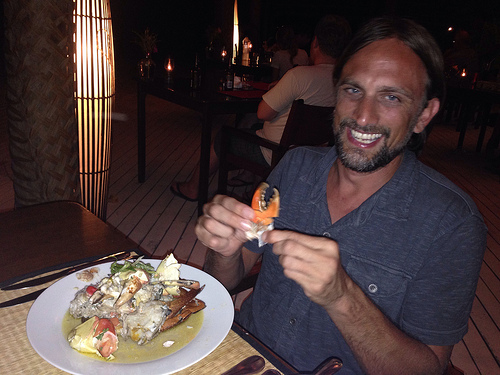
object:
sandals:
[167, 164, 215, 209]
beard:
[331, 121, 403, 173]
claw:
[251, 183, 281, 242]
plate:
[26, 257, 230, 373]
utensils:
[0, 250, 126, 308]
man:
[196, 31, 481, 373]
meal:
[62, 244, 200, 361]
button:
[341, 257, 445, 342]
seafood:
[238, 173, 284, 249]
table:
[0, 198, 309, 373]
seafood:
[85, 280, 172, 322]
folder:
[0, 187, 157, 292]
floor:
[102, 92, 499, 371]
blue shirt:
[234, 142, 486, 362]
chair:
[215, 102, 326, 192]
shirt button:
[366, 282, 377, 292]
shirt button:
[287, 317, 297, 324]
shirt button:
[320, 230, 330, 238]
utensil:
[3, 250, 103, 320]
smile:
[345, 127, 381, 144]